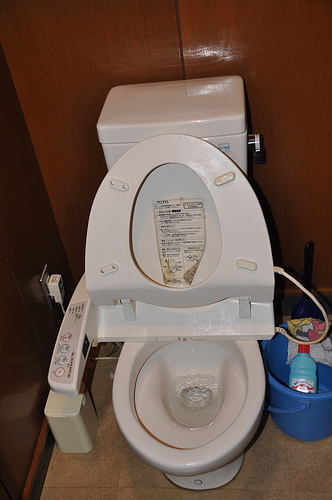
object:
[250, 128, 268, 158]
knob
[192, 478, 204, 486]
button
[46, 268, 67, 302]
socket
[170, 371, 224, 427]
water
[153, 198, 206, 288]
sign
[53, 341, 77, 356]
sign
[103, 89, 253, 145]
tank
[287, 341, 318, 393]
bottle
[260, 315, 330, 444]
bucket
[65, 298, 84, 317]
writing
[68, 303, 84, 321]
black writing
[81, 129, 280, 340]
lid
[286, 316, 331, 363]
rag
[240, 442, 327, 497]
floor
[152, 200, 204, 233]
writing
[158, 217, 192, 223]
writing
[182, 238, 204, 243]
writing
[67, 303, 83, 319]
sign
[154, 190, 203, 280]
black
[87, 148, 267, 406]
toilet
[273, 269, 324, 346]
cord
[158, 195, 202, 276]
writing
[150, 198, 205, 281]
writing